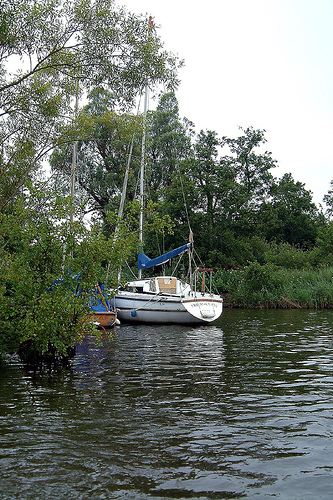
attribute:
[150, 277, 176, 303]
trim — brown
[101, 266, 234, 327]
boat — white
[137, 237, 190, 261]
pole — blue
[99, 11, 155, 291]
poles — tall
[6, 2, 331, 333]
greenery — lush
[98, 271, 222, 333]
boat — white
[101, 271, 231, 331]
boat — white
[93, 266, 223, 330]
boat — white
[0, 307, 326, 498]
water — green, murky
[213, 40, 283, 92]
sky — above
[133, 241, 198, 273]
part — blue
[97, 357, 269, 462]
water — green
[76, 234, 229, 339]
boat — white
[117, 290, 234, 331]
trim — brown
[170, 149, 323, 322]
area — lush wooded area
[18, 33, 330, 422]
day — bright, clear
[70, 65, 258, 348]
boat — white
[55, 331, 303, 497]
river — swamp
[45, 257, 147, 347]
sailboat — small, red, rusty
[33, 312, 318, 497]
river — marshy, dark